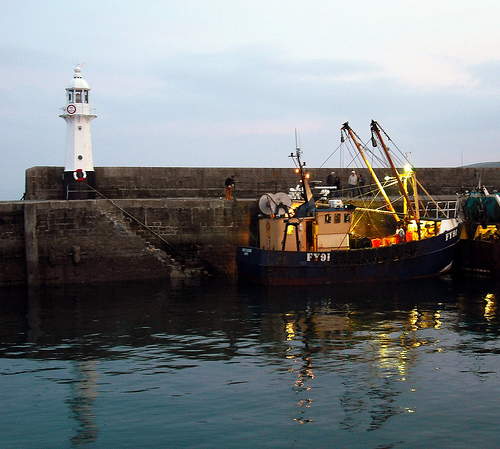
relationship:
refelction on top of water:
[72, 356, 99, 445] [1, 284, 492, 449]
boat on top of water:
[238, 123, 463, 285] [1, 284, 492, 449]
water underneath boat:
[1, 284, 492, 449] [238, 123, 463, 285]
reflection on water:
[275, 308, 356, 354] [1, 284, 492, 449]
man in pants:
[223, 175, 238, 202] [225, 186, 232, 201]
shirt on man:
[349, 175, 356, 185] [347, 171, 359, 198]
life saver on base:
[73, 168, 87, 183] [62, 171, 94, 198]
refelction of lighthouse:
[72, 356, 99, 445] [59, 60, 98, 200]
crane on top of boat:
[344, 122, 400, 223] [238, 123, 463, 285]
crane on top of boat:
[371, 120, 419, 223] [238, 123, 463, 285]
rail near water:
[88, 186, 178, 252] [1, 284, 492, 449]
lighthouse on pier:
[59, 60, 98, 200] [1, 200, 238, 281]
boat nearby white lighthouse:
[238, 123, 463, 285] [59, 60, 98, 200]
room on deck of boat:
[256, 207, 349, 250] [238, 123, 463, 285]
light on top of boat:
[400, 162, 415, 178] [238, 123, 463, 285]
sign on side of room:
[286, 223, 295, 236] [256, 207, 349, 250]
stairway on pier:
[70, 199, 188, 275] [1, 200, 238, 281]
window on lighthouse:
[77, 153, 84, 163] [59, 60, 98, 200]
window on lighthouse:
[77, 123, 83, 131] [59, 60, 98, 200]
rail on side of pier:
[88, 186, 178, 252] [1, 200, 238, 281]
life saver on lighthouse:
[73, 168, 87, 183] [59, 60, 98, 200]